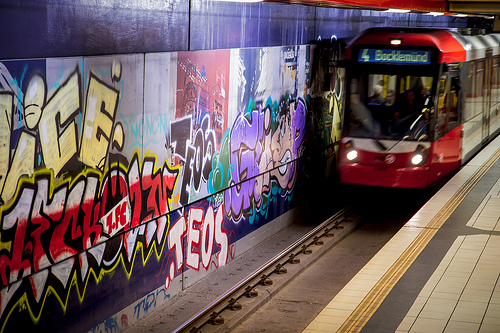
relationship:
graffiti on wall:
[1, 54, 349, 260] [5, 4, 331, 324]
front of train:
[338, 27, 462, 191] [335, 23, 500, 187]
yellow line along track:
[341, 144, 499, 319] [170, 209, 386, 333]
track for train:
[170, 209, 386, 333] [335, 23, 500, 187]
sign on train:
[364, 46, 444, 62] [335, 23, 500, 187]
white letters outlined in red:
[167, 207, 230, 291] [183, 207, 203, 211]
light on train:
[389, 37, 408, 45] [335, 23, 500, 187]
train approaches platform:
[335, 23, 500, 187] [303, 132, 499, 332]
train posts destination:
[335, 23, 500, 187] [360, 51, 427, 62]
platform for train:
[303, 132, 499, 332] [335, 23, 500, 187]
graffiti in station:
[1, 54, 349, 260] [1, 1, 500, 330]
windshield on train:
[349, 72, 436, 139] [335, 23, 500, 187]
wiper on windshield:
[391, 98, 429, 150] [349, 72, 436, 139]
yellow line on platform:
[341, 144, 499, 319] [303, 132, 499, 332]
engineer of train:
[395, 76, 429, 125] [335, 23, 500, 187]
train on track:
[335, 23, 500, 187] [170, 209, 386, 333]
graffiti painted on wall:
[1, 54, 349, 260] [5, 4, 331, 324]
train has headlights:
[335, 23, 500, 187] [346, 149, 422, 169]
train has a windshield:
[335, 23, 500, 187] [349, 72, 436, 139]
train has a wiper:
[335, 23, 500, 187] [391, 98, 429, 150]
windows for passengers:
[439, 54, 499, 138] [361, 78, 396, 95]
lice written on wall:
[2, 76, 124, 206] [5, 4, 331, 324]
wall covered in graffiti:
[5, 4, 331, 324] [1, 54, 349, 260]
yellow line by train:
[303, 132, 499, 332] [335, 23, 500, 187]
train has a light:
[335, 23, 500, 187] [389, 37, 408, 45]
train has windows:
[335, 23, 500, 187] [439, 54, 499, 138]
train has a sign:
[335, 23, 500, 187] [364, 46, 444, 62]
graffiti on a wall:
[1, 54, 349, 260] [5, 4, 331, 324]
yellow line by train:
[341, 144, 499, 319] [335, 23, 500, 187]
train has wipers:
[335, 23, 500, 187] [351, 98, 426, 153]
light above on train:
[389, 37, 408, 45] [335, 23, 500, 187]